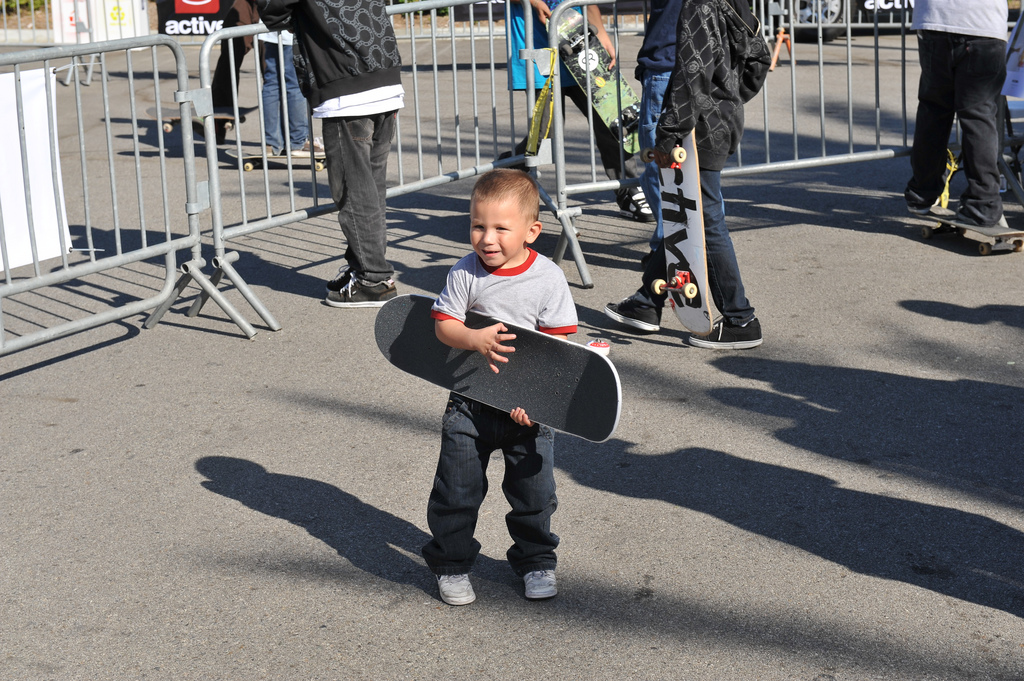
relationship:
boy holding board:
[403, 152, 594, 624] [353, 282, 647, 475]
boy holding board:
[414, 156, 589, 617] [371, 290, 628, 448]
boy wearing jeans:
[414, 156, 589, 617] [414, 374, 557, 574]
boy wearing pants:
[414, 156, 589, 617] [416, 394, 570, 578]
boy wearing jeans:
[414, 156, 589, 617] [414, 374, 566, 576]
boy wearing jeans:
[414, 158, 575, 582] [423, 379, 570, 581]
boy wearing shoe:
[403, 152, 594, 624] [425, 569, 486, 619]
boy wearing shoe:
[403, 152, 594, 624] [511, 571, 566, 613]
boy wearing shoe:
[414, 156, 589, 617] [431, 567, 483, 624]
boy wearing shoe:
[414, 156, 589, 617] [518, 562, 568, 615]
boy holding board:
[403, 152, 594, 624] [371, 290, 628, 448]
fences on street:
[24, 52, 303, 402] [33, 322, 295, 612]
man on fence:
[221, 2, 396, 311] [26, 34, 316, 283]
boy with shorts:
[418, 170, 580, 605] [433, 371, 516, 488]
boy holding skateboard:
[418, 170, 580, 605] [363, 231, 744, 517]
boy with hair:
[327, 123, 583, 579] [463, 157, 550, 207]